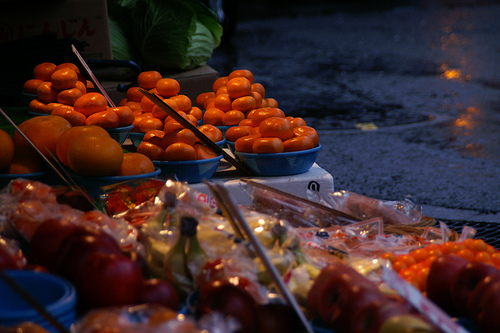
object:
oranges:
[12, 114, 73, 155]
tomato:
[56, 124, 112, 167]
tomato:
[24, 79, 44, 91]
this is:
[155, 78, 180, 97]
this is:
[231, 96, 256, 113]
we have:
[138, 71, 162, 89]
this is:
[34, 62, 57, 81]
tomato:
[235, 136, 258, 152]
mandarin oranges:
[258, 116, 294, 141]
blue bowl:
[234, 143, 323, 177]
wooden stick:
[137, 88, 252, 175]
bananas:
[163, 216, 212, 292]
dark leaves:
[125, 2, 197, 73]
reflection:
[337, 3, 497, 158]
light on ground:
[419, 1, 498, 164]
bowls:
[150, 154, 224, 184]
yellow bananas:
[244, 220, 321, 301]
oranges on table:
[226, 77, 251, 100]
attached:
[160, 216, 209, 276]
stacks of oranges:
[24, 62, 279, 128]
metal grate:
[355, 122, 379, 131]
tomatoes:
[30, 216, 77, 261]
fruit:
[3, 62, 316, 186]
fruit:
[2, 182, 500, 333]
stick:
[237, 178, 364, 226]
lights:
[0, 0, 497, 331]